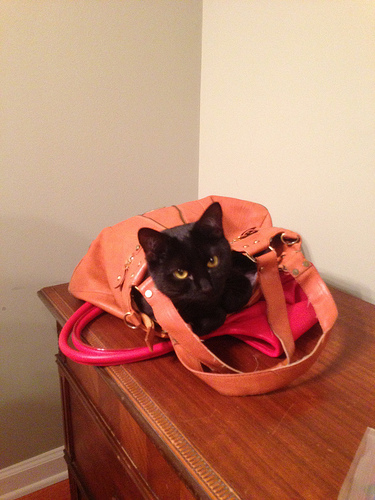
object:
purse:
[57, 260, 320, 367]